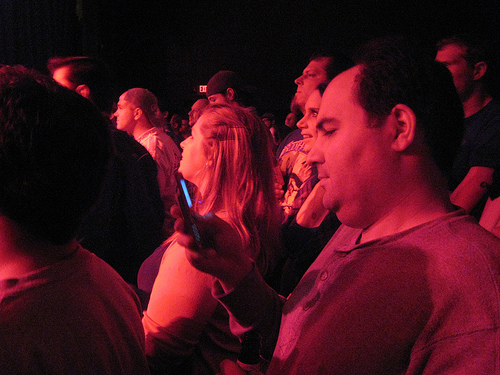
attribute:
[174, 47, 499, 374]
man — texting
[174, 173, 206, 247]
phone — cellphone, on, red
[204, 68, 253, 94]
cap — backwards, black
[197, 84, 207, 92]
sign — distant, exit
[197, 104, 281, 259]
hair — blonde, long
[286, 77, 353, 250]
woman — smiling